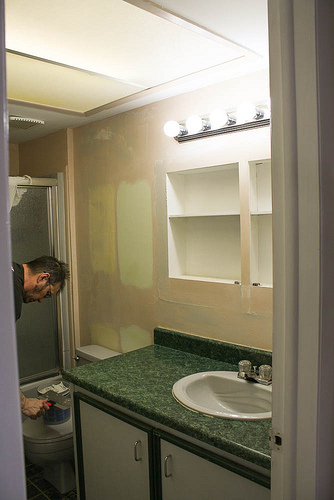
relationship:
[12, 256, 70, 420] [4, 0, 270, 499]
man in bathroom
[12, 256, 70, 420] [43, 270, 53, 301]
man wearing glasses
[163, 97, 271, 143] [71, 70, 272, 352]
lights on wall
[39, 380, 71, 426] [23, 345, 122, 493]
paint on toilet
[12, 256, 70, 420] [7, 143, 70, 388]
man next to shower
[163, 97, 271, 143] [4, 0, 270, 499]
lights in bathroom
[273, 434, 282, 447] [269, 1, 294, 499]
hole in door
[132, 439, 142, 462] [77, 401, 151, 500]
handle on door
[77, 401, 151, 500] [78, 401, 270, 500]
door on cupboard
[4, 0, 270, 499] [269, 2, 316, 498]
bathroom has door frame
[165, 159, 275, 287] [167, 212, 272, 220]
cabinet has shelves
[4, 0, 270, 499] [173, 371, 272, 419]
bathroom has sink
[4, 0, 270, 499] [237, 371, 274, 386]
bathroom has faucet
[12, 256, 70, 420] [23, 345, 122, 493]
man over toilet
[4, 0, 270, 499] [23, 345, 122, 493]
bathroom has toilet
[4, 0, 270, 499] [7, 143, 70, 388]
bathroom has shower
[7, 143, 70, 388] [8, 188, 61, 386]
shower has glass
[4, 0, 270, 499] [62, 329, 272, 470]
bathroom has counter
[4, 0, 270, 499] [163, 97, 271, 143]
bathroom has lights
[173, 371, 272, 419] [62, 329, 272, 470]
sink has counter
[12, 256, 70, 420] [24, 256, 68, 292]
man has hair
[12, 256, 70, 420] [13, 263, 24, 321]
man wearing shirt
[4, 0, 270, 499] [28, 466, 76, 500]
bathroom has tile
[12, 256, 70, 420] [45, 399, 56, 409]
man holding tool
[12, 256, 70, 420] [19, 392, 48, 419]
man has hand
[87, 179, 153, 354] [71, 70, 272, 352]
paint on wall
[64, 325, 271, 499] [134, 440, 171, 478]
vanity has handles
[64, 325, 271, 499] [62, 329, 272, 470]
vanity has counter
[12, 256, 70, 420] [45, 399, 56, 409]
man using tool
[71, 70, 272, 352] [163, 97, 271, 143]
wall has lights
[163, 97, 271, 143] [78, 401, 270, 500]
lights above cupboard